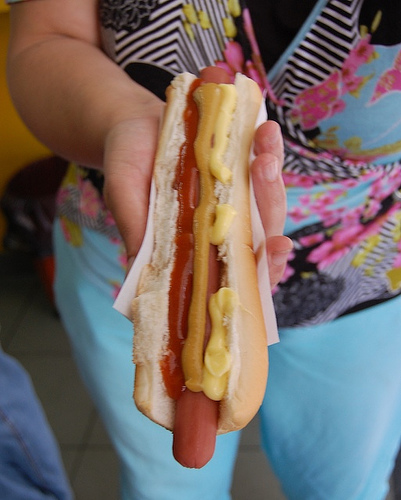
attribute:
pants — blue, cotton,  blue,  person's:
[54, 209, 399, 497]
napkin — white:
[118, 185, 153, 308]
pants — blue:
[58, 308, 393, 496]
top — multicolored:
[61, 25, 400, 291]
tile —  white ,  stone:
[14, 334, 104, 454]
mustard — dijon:
[177, 77, 217, 400]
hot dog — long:
[152, 65, 241, 474]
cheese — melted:
[207, 286, 233, 400]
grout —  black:
[69, 433, 94, 455]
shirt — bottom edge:
[90, 6, 387, 280]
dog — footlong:
[113, 47, 276, 383]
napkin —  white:
[114, 75, 303, 350]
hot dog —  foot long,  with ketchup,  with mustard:
[181, 52, 249, 471]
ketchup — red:
[175, 76, 196, 397]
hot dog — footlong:
[169, 61, 242, 475]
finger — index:
[264, 229, 295, 296]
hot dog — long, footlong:
[132, 62, 266, 468]